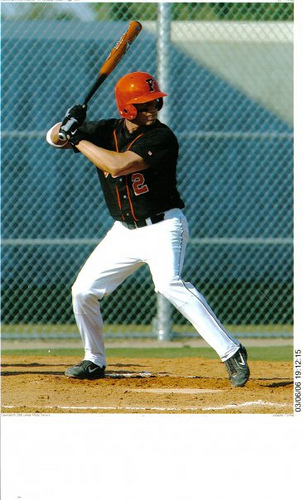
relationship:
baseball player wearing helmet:
[46, 71, 251, 388] [116, 67, 165, 117]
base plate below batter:
[128, 386, 224, 395] [45, 72, 249, 386]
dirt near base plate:
[3, 362, 290, 411] [128, 386, 224, 395]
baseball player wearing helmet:
[46, 71, 251, 388] [97, 61, 173, 110]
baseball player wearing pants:
[46, 71, 251, 388] [71, 207, 240, 368]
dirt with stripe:
[3, 362, 290, 411] [6, 398, 293, 410]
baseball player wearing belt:
[46, 71, 251, 388] [109, 212, 168, 228]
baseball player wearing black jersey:
[46, 71, 251, 388] [70, 117, 186, 226]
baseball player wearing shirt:
[46, 71, 251, 388] [88, 117, 205, 224]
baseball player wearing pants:
[46, 71, 251, 388] [81, 237, 261, 385]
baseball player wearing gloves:
[46, 71, 251, 388] [52, 97, 92, 154]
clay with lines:
[11, 378, 292, 419] [31, 400, 288, 417]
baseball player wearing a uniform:
[46, 71, 251, 388] [69, 120, 185, 218]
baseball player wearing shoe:
[46, 71, 251, 388] [62, 359, 107, 379]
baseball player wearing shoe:
[46, 71, 251, 388] [218, 342, 251, 387]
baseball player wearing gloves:
[46, 71, 251, 388] [56, 98, 88, 147]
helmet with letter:
[90, 68, 173, 110] [143, 76, 158, 91]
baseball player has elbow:
[46, 71, 251, 388] [107, 161, 126, 175]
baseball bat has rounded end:
[70, 17, 144, 117] [100, 16, 143, 74]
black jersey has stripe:
[70, 117, 185, 223] [106, 127, 139, 211]